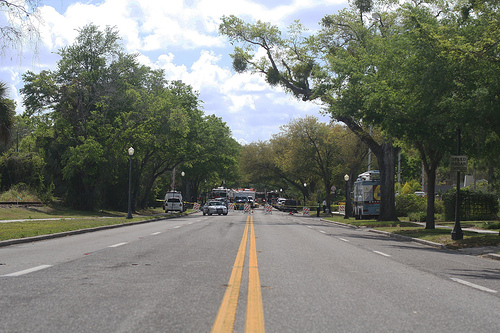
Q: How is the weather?
A: It is cloudy.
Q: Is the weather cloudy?
A: Yes, it is cloudy.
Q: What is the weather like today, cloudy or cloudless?
A: It is cloudy.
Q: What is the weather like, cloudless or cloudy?
A: It is cloudy.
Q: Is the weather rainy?
A: No, it is cloudy.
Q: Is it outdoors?
A: Yes, it is outdoors.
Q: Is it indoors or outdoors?
A: It is outdoors.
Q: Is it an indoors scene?
A: No, it is outdoors.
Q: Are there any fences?
A: No, there are no fences.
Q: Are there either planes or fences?
A: No, there are no fences or planes.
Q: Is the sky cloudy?
A: Yes, the sky is cloudy.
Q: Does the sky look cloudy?
A: Yes, the sky is cloudy.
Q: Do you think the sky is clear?
A: No, the sky is cloudy.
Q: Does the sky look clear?
A: No, the sky is cloudy.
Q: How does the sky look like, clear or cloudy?
A: The sky is cloudy.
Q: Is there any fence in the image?
A: No, there are no fences.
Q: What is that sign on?
A: The sign is on the pole.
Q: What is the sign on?
A: The sign is on the pole.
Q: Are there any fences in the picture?
A: No, there are no fences.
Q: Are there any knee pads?
A: No, there are no knee pads.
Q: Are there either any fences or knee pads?
A: No, there are no knee pads or fences.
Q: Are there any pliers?
A: No, there are no pliers.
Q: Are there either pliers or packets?
A: No, there are no pliers or packets.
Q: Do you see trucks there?
A: Yes, there is a truck.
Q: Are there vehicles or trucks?
A: Yes, there is a truck.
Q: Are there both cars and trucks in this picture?
A: Yes, there are both a truck and a car.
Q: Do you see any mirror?
A: No, there are no mirrors.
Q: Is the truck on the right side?
A: Yes, the truck is on the right of the image.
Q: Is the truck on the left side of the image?
A: No, the truck is on the right of the image.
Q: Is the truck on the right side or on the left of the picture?
A: The truck is on the right of the image.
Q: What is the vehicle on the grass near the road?
A: The vehicle is a truck.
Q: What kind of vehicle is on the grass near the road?
A: The vehicle is a truck.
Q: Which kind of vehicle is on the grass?
A: The vehicle is a truck.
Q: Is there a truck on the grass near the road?
A: Yes, there is a truck on the grass.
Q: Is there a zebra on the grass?
A: No, there is a truck on the grass.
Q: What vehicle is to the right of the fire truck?
A: The vehicle is a truck.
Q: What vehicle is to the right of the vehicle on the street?
A: The vehicle is a truck.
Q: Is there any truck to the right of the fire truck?
A: Yes, there is a truck to the right of the fire truck.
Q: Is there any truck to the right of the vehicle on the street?
A: Yes, there is a truck to the right of the fire truck.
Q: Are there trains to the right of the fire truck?
A: No, there is a truck to the right of the fire truck.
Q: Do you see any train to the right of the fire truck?
A: No, there is a truck to the right of the fire truck.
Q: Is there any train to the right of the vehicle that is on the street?
A: No, there is a truck to the right of the fire truck.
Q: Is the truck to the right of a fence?
A: No, the truck is to the right of a fire truck.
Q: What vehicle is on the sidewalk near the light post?
A: The vehicle is a truck.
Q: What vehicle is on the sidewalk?
A: The vehicle is a truck.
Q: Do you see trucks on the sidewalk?
A: Yes, there is a truck on the sidewalk.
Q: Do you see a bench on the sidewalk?
A: No, there is a truck on the sidewalk.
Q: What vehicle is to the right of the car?
A: The vehicle is a truck.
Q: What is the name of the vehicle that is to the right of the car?
A: The vehicle is a truck.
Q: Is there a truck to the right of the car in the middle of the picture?
A: Yes, there is a truck to the right of the car.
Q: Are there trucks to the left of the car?
A: No, the truck is to the right of the car.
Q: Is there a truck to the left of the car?
A: No, the truck is to the right of the car.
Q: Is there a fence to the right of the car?
A: No, there is a truck to the right of the car.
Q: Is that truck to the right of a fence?
A: No, the truck is to the right of the car.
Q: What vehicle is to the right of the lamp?
A: The vehicle is a truck.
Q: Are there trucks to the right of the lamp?
A: Yes, there is a truck to the right of the lamp.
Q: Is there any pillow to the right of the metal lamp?
A: No, there is a truck to the right of the lamp.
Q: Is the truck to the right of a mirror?
A: No, the truck is to the right of the lamp.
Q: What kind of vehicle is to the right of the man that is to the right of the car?
A: The vehicle is a truck.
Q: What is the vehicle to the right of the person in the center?
A: The vehicle is a truck.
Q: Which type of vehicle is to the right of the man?
A: The vehicle is a truck.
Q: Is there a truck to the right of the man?
A: Yes, there is a truck to the right of the man.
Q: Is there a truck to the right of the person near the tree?
A: Yes, there is a truck to the right of the man.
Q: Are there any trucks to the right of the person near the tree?
A: Yes, there is a truck to the right of the man.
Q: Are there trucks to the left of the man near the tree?
A: No, the truck is to the right of the man.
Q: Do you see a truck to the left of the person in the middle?
A: No, the truck is to the right of the man.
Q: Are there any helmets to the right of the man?
A: No, there is a truck to the right of the man.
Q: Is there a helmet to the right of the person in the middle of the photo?
A: No, there is a truck to the right of the man.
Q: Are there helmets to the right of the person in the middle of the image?
A: No, there is a truck to the right of the man.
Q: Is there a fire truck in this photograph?
A: Yes, there is a fire truck.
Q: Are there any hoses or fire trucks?
A: Yes, there is a fire truck.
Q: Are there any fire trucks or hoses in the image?
A: Yes, there is a fire truck.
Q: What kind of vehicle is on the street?
A: The vehicle is a fire truck.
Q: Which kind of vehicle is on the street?
A: The vehicle is a fire truck.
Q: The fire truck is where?
A: The fire truck is on the street.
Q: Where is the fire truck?
A: The fire truck is on the street.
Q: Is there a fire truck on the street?
A: Yes, there is a fire truck on the street.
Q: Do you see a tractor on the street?
A: No, there is a fire truck on the street.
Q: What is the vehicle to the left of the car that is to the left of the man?
A: The vehicle is a fire truck.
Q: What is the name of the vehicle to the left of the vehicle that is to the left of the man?
A: The vehicle is a fire truck.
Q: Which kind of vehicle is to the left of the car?
A: The vehicle is a fire truck.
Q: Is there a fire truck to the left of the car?
A: Yes, there is a fire truck to the left of the car.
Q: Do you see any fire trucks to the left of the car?
A: Yes, there is a fire truck to the left of the car.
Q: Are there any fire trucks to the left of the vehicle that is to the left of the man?
A: Yes, there is a fire truck to the left of the car.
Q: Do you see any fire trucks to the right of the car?
A: No, the fire truck is to the left of the car.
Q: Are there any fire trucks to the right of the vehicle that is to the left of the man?
A: No, the fire truck is to the left of the car.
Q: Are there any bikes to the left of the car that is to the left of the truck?
A: No, there is a fire truck to the left of the car.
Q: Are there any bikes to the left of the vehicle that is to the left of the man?
A: No, there is a fire truck to the left of the car.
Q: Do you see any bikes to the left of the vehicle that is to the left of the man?
A: No, there is a fire truck to the left of the car.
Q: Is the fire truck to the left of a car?
A: Yes, the fire truck is to the left of a car.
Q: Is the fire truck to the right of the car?
A: No, the fire truck is to the left of the car.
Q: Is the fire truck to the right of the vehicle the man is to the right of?
A: No, the fire truck is to the left of the car.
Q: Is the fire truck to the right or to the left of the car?
A: The fire truck is to the left of the car.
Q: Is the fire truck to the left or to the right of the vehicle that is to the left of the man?
A: The fire truck is to the left of the car.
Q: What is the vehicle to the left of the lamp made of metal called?
A: The vehicle is a fire truck.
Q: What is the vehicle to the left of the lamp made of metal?
A: The vehicle is a fire truck.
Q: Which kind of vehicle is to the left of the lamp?
A: The vehicle is a fire truck.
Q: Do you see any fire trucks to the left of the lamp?
A: Yes, there is a fire truck to the left of the lamp.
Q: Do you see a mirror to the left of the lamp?
A: No, there is a fire truck to the left of the lamp.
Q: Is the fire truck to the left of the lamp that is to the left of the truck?
A: Yes, the fire truck is to the left of the lamp.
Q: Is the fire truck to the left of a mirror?
A: No, the fire truck is to the left of the lamp.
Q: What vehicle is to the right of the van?
A: The vehicle is a fire truck.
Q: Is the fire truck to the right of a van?
A: Yes, the fire truck is to the right of a van.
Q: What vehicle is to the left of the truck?
A: The vehicle is a fire truck.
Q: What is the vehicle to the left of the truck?
A: The vehicle is a fire truck.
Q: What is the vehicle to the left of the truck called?
A: The vehicle is a fire truck.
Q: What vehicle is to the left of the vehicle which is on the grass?
A: The vehicle is a fire truck.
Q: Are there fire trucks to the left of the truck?
A: Yes, there is a fire truck to the left of the truck.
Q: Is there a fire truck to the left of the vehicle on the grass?
A: Yes, there is a fire truck to the left of the truck.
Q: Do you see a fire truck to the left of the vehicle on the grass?
A: Yes, there is a fire truck to the left of the truck.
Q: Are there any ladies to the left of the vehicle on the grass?
A: No, there is a fire truck to the left of the truck.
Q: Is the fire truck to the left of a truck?
A: Yes, the fire truck is to the left of a truck.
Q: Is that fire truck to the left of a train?
A: No, the fire truck is to the left of a truck.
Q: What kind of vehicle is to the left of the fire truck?
A: The vehicle is a van.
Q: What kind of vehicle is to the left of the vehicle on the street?
A: The vehicle is a van.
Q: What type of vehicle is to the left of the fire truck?
A: The vehicle is a van.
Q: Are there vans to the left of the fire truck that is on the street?
A: Yes, there is a van to the left of the fire truck.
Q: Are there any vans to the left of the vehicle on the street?
A: Yes, there is a van to the left of the fire truck.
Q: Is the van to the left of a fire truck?
A: Yes, the van is to the left of a fire truck.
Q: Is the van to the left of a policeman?
A: No, the van is to the left of a fire truck.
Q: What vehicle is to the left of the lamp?
A: The vehicle is a van.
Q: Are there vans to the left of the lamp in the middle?
A: Yes, there is a van to the left of the lamp.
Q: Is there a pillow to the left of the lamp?
A: No, there is a van to the left of the lamp.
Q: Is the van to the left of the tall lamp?
A: Yes, the van is to the left of the lamp.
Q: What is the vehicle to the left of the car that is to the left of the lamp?
A: The vehicle is a van.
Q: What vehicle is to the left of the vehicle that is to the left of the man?
A: The vehicle is a van.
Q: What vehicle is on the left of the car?
A: The vehicle is a van.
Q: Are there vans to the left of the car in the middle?
A: Yes, there is a van to the left of the car.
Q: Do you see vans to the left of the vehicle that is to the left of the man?
A: Yes, there is a van to the left of the car.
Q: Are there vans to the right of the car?
A: No, the van is to the left of the car.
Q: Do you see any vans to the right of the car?
A: No, the van is to the left of the car.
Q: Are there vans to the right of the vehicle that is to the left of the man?
A: No, the van is to the left of the car.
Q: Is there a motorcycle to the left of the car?
A: No, there is a van to the left of the car.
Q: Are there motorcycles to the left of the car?
A: No, there is a van to the left of the car.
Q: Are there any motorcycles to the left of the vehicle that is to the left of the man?
A: No, there is a van to the left of the car.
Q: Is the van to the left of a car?
A: Yes, the van is to the left of a car.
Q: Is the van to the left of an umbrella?
A: No, the van is to the left of a car.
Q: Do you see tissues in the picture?
A: No, there are no tissues.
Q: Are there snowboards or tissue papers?
A: No, there are no tissue papers or snowboards.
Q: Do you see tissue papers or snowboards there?
A: No, there are no tissue papers or snowboards.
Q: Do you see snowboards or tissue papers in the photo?
A: No, there are no tissue papers or snowboards.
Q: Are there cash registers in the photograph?
A: No, there are no cash registers.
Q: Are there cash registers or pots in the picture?
A: No, there are no cash registers or pots.